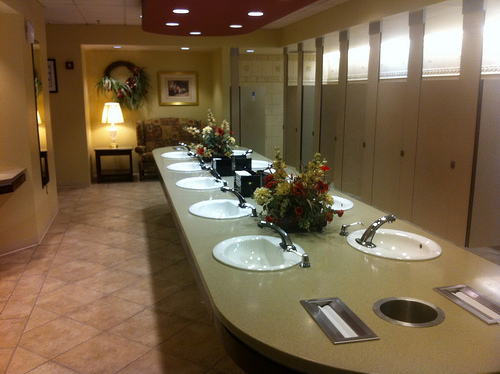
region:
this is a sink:
[225, 227, 292, 265]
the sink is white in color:
[239, 243, 264, 261]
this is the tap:
[256, 217, 296, 248]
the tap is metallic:
[256, 218, 296, 245]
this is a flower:
[275, 160, 320, 216]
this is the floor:
[68, 210, 139, 343]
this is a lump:
[101, 99, 128, 123]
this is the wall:
[4, 66, 28, 148]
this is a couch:
[141, 117, 172, 140]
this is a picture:
[159, 67, 200, 103]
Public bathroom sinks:
[160, 139, 457, 277]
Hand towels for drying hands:
[299, 288, 380, 355]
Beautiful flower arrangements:
[252, 146, 346, 240]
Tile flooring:
[58, 186, 163, 367]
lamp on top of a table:
[91, 97, 135, 182]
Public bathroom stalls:
[273, 50, 499, 245]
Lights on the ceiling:
[158, 1, 265, 38]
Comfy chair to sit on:
[133, 116, 214, 182]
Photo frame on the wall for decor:
[153, 64, 204, 109]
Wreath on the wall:
[93, 56, 152, 113]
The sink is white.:
[201, 227, 302, 301]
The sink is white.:
[185, 208, 332, 318]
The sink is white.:
[187, 188, 284, 285]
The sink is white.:
[168, 144, 346, 359]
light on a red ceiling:
[170, 1, 191, 19]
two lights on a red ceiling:
[163, 6, 189, 28]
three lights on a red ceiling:
[163, 4, 208, 36]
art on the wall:
[156, 68, 201, 106]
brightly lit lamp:
[98, 101, 127, 150]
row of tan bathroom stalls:
[285, 13, 497, 245]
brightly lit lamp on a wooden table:
[90, 101, 131, 183]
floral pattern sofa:
[136, 116, 207, 173]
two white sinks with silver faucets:
[185, 182, 310, 278]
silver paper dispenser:
[298, 286, 380, 351]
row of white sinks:
[170, 141, 301, 282]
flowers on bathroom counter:
[257, 148, 342, 233]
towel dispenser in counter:
[303, 288, 375, 355]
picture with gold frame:
[154, 66, 203, 115]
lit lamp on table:
[90, 94, 140, 181]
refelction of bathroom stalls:
[275, 75, 492, 201]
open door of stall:
[294, 76, 320, 171]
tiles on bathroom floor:
[64, 230, 139, 357]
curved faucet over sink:
[250, 211, 300, 251]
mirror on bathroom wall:
[27, 69, 55, 196]